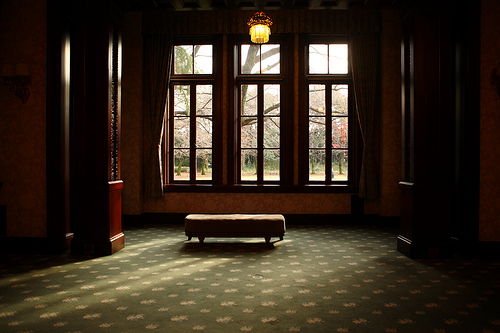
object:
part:
[245, 271, 273, 289]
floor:
[0, 224, 500, 333]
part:
[267, 85, 284, 98]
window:
[229, 81, 293, 184]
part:
[262, 225, 281, 246]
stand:
[183, 213, 284, 247]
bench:
[183, 213, 286, 247]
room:
[0, 0, 500, 332]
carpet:
[0, 221, 500, 333]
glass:
[241, 44, 281, 75]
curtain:
[140, 19, 175, 202]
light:
[246, 11, 273, 44]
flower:
[332, 144, 339, 148]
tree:
[309, 85, 349, 176]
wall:
[121, 0, 400, 229]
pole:
[45, 0, 74, 255]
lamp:
[0, 60, 34, 105]